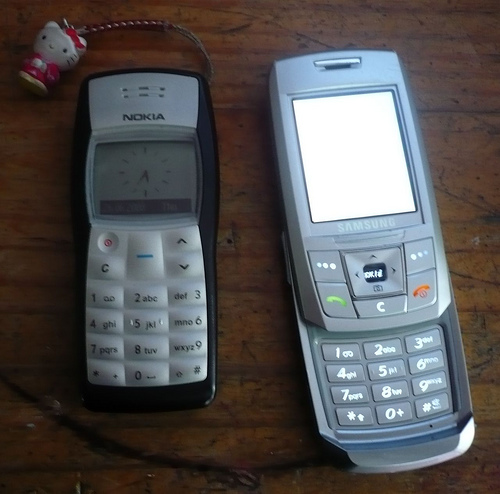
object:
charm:
[18, 20, 86, 97]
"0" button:
[385, 407, 396, 420]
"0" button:
[124, 362, 169, 387]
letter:
[376, 301, 385, 312]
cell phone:
[268, 48, 476, 476]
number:
[194, 290, 201, 300]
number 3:
[413, 337, 423, 349]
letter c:
[376, 302, 385, 313]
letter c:
[101, 264, 110, 273]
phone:
[70, 66, 220, 413]